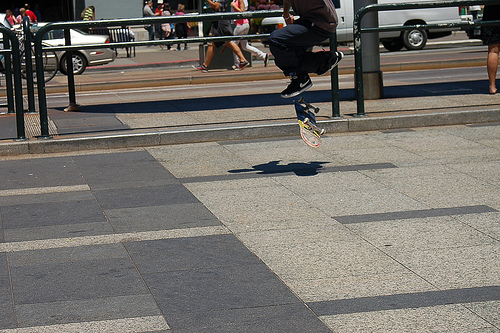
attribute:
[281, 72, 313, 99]
black shoe — white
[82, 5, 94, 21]
shirt — yellow, black, striped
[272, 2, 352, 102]
skater — jumping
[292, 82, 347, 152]
skater — upside down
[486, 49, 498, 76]
calve — womans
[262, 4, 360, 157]
man — tennis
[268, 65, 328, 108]
shoes — black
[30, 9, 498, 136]
railing — black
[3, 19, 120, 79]
sedan — silver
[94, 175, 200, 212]
tile — darker, concrete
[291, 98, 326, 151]
skateboard — airborne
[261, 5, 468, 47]
truck — white, pickup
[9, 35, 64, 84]
tire — large, round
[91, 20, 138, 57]
bench — metal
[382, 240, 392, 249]
spot — black